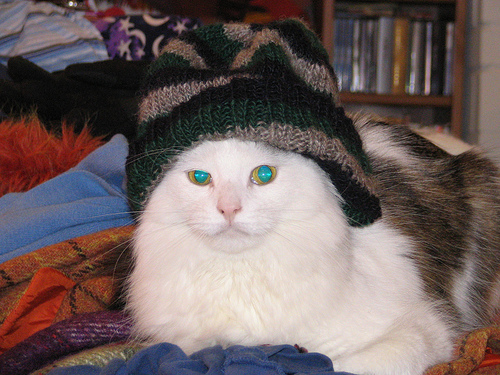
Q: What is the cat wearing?
A: Knit hat.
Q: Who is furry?
A: The cat.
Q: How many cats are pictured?
A: One.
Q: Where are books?
A: On a bookshelf.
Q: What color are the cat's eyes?
A: Yellow and blue.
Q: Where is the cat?
A: On a bed.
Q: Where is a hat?
A: On cat's head.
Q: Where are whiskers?
A: On cat's face.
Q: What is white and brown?
A: A cat.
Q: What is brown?
A: The bookshelf.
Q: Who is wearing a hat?
A: Cat.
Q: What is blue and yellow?
A: Cat's eyes.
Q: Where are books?
A: On a shelf.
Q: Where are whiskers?
A: On cat's face.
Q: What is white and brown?
A: The cat.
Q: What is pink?
A: Cat's nose.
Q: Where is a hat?
A: On cat's head.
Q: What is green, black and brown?
A: The hat.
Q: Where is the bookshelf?
A: Behind the cat.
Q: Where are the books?
A: On shelf.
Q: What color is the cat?
A: White.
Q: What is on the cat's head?
A: A hat.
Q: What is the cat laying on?
A: Clothing.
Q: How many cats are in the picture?
A: 1.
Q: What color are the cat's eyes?
A: Green.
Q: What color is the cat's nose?
A: Pink.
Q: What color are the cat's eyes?
A: Blue.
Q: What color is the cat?
A: White and gray.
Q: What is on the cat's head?
A: Hat.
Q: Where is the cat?
A: On the bed.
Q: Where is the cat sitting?
A: On the bed.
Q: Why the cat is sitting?
A: Resting.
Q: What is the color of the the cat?
A: White and brown.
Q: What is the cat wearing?
A: Beanie hat.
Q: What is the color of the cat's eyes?
A: Green.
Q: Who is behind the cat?
A: No one.